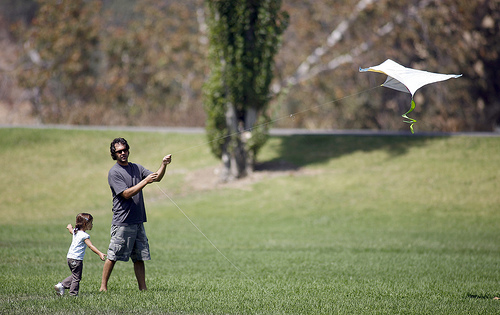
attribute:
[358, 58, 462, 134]
kite — white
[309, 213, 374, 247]
grass — green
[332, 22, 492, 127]
kite — white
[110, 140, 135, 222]
shirt — blue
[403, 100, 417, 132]
ribbon — green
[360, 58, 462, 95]
kite — white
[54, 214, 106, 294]
girl — little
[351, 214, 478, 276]
grass — green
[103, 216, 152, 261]
shorts — blue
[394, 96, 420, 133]
ribbon — green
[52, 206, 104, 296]
girl — little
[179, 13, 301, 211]
tree — green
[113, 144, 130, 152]
sunglasses — black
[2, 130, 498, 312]
grass — green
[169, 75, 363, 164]
string — thin, white